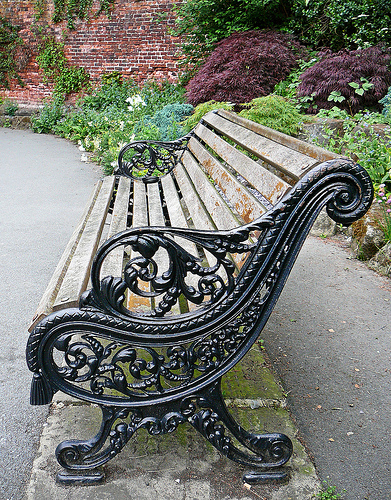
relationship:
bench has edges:
[25, 109, 374, 487] [26, 109, 373, 485]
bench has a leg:
[25, 109, 374, 487] [54, 404, 138, 486]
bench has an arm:
[25, 109, 374, 487] [79, 218, 268, 324]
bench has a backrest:
[25, 109, 374, 487] [163, 107, 373, 336]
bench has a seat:
[25, 109, 374, 487] [28, 173, 218, 351]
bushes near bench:
[33, 0, 390, 253] [25, 109, 374, 487]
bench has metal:
[25, 109, 374, 487] [27, 109, 374, 487]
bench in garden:
[25, 109, 374, 487] [1, 0, 390, 279]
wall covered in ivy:
[1, 2, 206, 110] [0, 0, 211, 107]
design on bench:
[26, 107, 373, 484] [25, 109, 374, 487]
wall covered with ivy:
[1, 2, 206, 110] [0, 0, 211, 107]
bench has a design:
[25, 109, 374, 487] [26, 107, 373, 484]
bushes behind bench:
[33, 0, 390, 253] [25, 109, 374, 487]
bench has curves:
[25, 109, 374, 487] [25, 107, 374, 486]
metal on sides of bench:
[27, 109, 374, 487] [25, 109, 374, 487]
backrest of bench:
[163, 107, 373, 336] [25, 109, 374, 487]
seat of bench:
[28, 173, 218, 351] [25, 109, 374, 487]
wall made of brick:
[1, 2, 206, 110] [0, 0, 208, 103]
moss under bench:
[93, 252, 313, 469] [25, 109, 374, 487]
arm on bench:
[79, 218, 268, 324] [25, 109, 374, 487]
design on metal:
[26, 107, 373, 484] [27, 109, 374, 487]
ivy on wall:
[0, 0, 211, 107] [1, 2, 206, 110]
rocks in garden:
[308, 194, 390, 278] [1, 0, 390, 279]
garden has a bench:
[1, 0, 390, 279] [25, 109, 374, 487]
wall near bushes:
[1, 2, 206, 110] [33, 0, 390, 253]